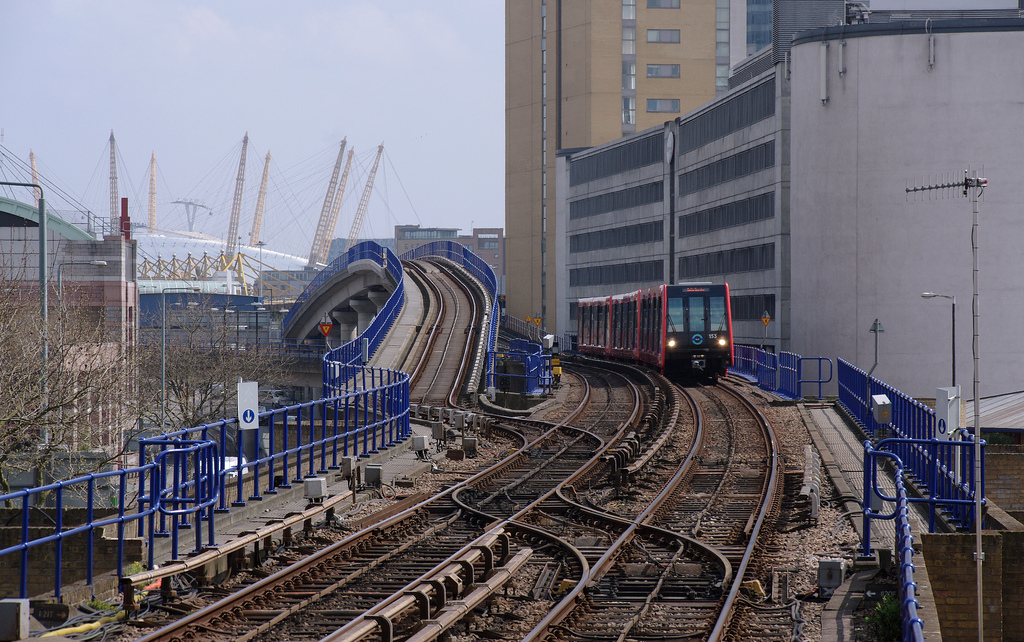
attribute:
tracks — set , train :
[150, 387, 810, 638]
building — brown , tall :
[501, 1, 735, 358]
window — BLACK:
[707, 282, 733, 343]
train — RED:
[655, 275, 733, 371]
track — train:
[345, 222, 499, 402]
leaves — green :
[216, 340, 271, 367]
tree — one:
[211, 336, 259, 406]